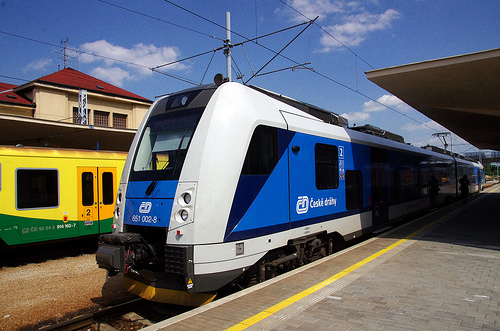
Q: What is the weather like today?
A: It is clear.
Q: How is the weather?
A: It is clear.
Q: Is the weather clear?
A: Yes, it is clear.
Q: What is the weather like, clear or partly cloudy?
A: It is clear.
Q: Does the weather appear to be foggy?
A: No, it is clear.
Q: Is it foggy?
A: No, it is clear.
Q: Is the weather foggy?
A: No, it is clear.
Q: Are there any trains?
A: Yes, there is a train.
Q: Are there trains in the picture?
A: Yes, there is a train.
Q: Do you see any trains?
A: Yes, there is a train.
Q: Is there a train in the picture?
A: Yes, there is a train.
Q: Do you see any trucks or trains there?
A: Yes, there is a train.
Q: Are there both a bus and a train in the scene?
A: No, there is a train but no buses.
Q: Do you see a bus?
A: No, there are no buses.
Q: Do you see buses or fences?
A: No, there are no buses or fences.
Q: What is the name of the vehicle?
A: The vehicle is a train.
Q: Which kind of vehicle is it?
A: The vehicle is a train.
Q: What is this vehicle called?
A: This is a train.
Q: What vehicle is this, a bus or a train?
A: This is a train.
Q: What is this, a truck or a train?
A: This is a train.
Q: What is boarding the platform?
A: The train is boarding the platform.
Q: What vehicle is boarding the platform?
A: The vehicle is a train.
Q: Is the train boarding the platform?
A: Yes, the train is boarding the platform.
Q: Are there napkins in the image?
A: No, there are no napkins.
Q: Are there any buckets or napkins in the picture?
A: No, there are no napkins or buckets.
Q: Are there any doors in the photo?
A: Yes, there is a door.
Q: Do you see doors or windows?
A: Yes, there is a door.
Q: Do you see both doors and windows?
A: Yes, there are both a door and a window.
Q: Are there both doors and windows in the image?
A: Yes, there are both a door and a window.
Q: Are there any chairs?
A: No, there are no chairs.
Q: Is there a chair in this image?
A: No, there are no chairs.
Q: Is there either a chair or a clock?
A: No, there are no chairs or clocks.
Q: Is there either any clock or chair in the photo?
A: No, there are no chairs or clocks.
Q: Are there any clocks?
A: No, there are no clocks.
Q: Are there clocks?
A: No, there are no clocks.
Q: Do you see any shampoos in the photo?
A: No, there are no shampoos.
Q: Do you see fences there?
A: No, there are no fences.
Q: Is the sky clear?
A: Yes, the sky is clear.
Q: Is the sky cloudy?
A: No, the sky is clear.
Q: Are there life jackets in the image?
A: No, there are no life jackets.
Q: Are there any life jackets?
A: No, there are no life jackets.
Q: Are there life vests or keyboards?
A: No, there are no life vests or keyboards.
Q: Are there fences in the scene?
A: No, there are no fences.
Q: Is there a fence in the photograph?
A: No, there are no fences.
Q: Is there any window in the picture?
A: Yes, there is a window.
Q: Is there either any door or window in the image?
A: Yes, there is a window.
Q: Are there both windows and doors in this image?
A: Yes, there are both a window and doors.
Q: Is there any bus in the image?
A: No, there are no buses.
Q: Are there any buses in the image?
A: No, there are no buses.